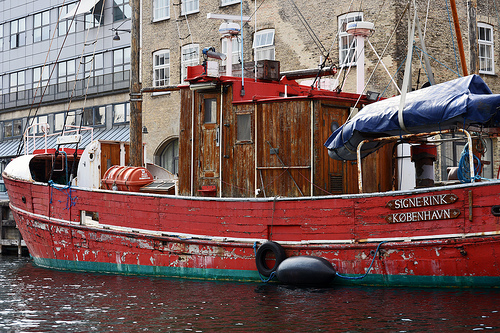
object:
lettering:
[385, 209, 459, 224]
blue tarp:
[323, 74, 500, 161]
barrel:
[100, 165, 153, 192]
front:
[0, 149, 78, 175]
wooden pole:
[128, 0, 145, 167]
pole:
[354, 34, 364, 95]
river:
[0, 289, 500, 333]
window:
[11, 19, 24, 50]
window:
[31, 8, 49, 41]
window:
[58, 3, 78, 36]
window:
[8, 70, 25, 103]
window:
[28, 65, 55, 101]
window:
[55, 58, 75, 96]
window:
[85, 50, 102, 93]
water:
[0, 286, 499, 332]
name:
[385, 193, 459, 210]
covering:
[324, 74, 500, 162]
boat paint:
[2, 172, 499, 289]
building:
[2, 0, 499, 176]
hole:
[21, 195, 26, 203]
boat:
[2, 47, 499, 290]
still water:
[2, 276, 166, 329]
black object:
[276, 255, 337, 288]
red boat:
[3, 64, 500, 294]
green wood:
[27, 253, 500, 289]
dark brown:
[179, 83, 389, 199]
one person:
[411, 142, 441, 189]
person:
[409, 136, 436, 189]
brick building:
[143, 12, 181, 162]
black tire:
[254, 240, 287, 278]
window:
[339, 10, 367, 64]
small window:
[231, 110, 254, 144]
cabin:
[177, 59, 396, 197]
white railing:
[21, 123, 93, 156]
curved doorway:
[152, 134, 180, 174]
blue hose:
[451, 141, 482, 184]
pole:
[466, 137, 476, 183]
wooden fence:
[63, 220, 119, 254]